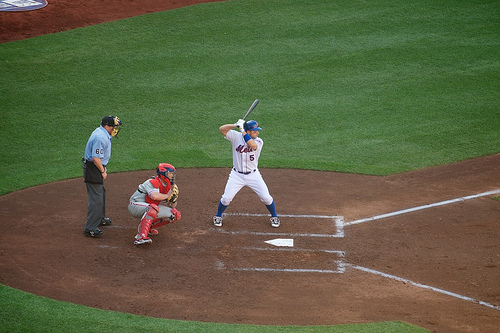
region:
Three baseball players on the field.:
[57, 53, 333, 298]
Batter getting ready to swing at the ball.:
[209, 85, 284, 237]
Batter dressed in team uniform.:
[208, 84, 291, 236]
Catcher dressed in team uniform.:
[126, 146, 191, 249]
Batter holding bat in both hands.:
[207, 80, 289, 234]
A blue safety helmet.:
[235, 107, 269, 137]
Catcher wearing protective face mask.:
[152, 159, 182, 185]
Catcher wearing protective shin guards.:
[120, 150, 189, 249]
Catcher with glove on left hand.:
[126, 147, 198, 254]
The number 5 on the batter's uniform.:
[213, 87, 285, 239]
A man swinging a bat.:
[216, 97, 283, 232]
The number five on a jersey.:
[247, 152, 256, 162]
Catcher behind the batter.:
[122, 155, 192, 257]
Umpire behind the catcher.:
[81, 105, 121, 248]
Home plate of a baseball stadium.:
[263, 230, 295, 251]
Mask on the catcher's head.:
[156, 159, 178, 185]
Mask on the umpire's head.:
[96, 105, 126, 141]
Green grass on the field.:
[182, 27, 440, 91]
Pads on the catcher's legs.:
[135, 196, 162, 253]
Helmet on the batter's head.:
[244, 115, 266, 133]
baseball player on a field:
[210, 97, 284, 231]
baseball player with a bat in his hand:
[211, 97, 281, 229]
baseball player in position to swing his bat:
[211, 97, 281, 229]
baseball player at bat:
[208, 99, 284, 230]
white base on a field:
[261, 234, 296, 248]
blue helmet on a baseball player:
[243, 117, 264, 132]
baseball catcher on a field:
[125, 161, 184, 246]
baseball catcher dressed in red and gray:
[125, 160, 184, 245]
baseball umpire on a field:
[81, 113, 126, 240]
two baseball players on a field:
[126, 98, 289, 248]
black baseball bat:
[234, 95, 261, 129]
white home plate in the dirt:
[261, 235, 296, 249]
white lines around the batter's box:
[216, 207, 347, 275]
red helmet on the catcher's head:
[154, 158, 176, 189]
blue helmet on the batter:
[242, 116, 262, 131]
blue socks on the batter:
[215, 197, 278, 219]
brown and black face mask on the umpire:
[110, 114, 121, 140]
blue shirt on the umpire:
[81, 122, 113, 168]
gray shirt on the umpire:
[85, 180, 107, 230]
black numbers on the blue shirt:
[93, 144, 106, 157]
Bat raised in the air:
[253, 101, 256, 104]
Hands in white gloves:
[237, 121, 242, 126]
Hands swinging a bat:
[239, 121, 244, 124]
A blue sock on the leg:
[271, 206, 274, 212]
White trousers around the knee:
[265, 196, 270, 201]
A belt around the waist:
[241, 171, 248, 174]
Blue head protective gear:
[248, 121, 253, 127]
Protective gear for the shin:
[143, 225, 147, 235]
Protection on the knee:
[172, 210, 177, 215]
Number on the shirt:
[251, 154, 254, 160]